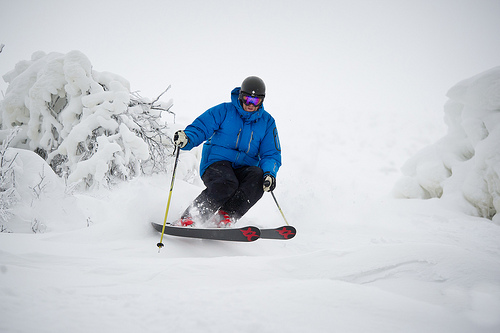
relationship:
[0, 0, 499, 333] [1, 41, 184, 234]
snow covered bush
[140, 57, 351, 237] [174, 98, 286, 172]
man wearing blue coat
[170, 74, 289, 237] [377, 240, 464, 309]
man skiing in thick snow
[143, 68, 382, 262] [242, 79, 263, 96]
man's helmet black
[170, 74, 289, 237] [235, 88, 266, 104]
man wearing pair of goggles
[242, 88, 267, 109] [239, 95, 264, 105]
goggles are black framed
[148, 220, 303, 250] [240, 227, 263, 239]
skis of skis are black and red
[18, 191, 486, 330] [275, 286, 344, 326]
ground covered with thick snow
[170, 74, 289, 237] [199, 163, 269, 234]
man wearing black pants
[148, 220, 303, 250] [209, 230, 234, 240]
skis are black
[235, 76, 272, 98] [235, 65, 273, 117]
black helmet on persons head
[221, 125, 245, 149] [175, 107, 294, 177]
blue colored jacket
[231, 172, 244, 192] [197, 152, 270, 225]
black ski pants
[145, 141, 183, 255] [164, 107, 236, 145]
ski pole in a gloved hand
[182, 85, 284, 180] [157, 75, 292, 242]
coat on person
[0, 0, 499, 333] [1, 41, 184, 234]
snow on bush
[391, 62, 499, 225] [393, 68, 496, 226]
snow on bush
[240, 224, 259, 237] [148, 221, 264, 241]
design on ski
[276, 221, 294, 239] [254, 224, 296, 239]
design on ski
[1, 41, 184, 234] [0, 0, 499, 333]
bush covered with snow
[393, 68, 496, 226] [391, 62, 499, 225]
bush covered with snow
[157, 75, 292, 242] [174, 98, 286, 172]
person wearing coat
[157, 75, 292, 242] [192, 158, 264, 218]
person wearing pants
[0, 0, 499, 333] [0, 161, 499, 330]
snow on ski slope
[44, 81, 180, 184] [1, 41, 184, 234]
limbs on bush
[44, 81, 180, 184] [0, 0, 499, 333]
limbs sticking out of snow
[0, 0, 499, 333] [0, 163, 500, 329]
snow on ground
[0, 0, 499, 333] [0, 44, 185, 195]
snow on tree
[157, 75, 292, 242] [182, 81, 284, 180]
person wearing jacket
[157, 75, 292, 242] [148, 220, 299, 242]
person on skis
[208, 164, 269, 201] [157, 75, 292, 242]
knees on person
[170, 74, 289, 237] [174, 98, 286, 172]
man wearing coat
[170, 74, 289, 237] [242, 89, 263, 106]
man wearing goggles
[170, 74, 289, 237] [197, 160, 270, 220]
man wearing pants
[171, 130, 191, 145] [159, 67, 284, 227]
hand on man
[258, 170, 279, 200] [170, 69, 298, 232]
left hand on man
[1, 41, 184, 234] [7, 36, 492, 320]
bush covered in snow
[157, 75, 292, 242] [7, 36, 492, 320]
person skiing on snow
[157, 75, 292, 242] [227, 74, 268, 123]
person wearing helmet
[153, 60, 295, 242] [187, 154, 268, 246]
person wearing pants